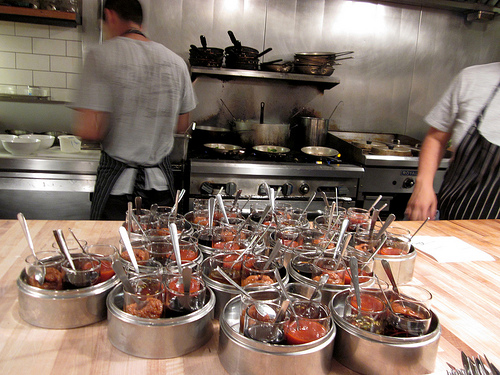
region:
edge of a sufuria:
[238, 336, 275, 366]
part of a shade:
[68, 338, 82, 352]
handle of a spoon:
[263, 272, 290, 296]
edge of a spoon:
[322, 220, 362, 282]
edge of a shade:
[102, 355, 124, 365]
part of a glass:
[299, 292, 322, 329]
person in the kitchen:
[66, 13, 201, 161]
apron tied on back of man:
[101, 150, 181, 195]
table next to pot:
[455, 276, 482, 299]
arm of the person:
[383, 119, 460, 230]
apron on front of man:
[446, 118, 496, 176]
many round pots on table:
[96, 186, 403, 354]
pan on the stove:
[311, 136, 339, 163]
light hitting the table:
[451, 286, 481, 338]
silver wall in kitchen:
[368, 36, 424, 73]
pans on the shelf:
[206, 38, 348, 88]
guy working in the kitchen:
[66, 19, 196, 171]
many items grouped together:
[113, 185, 387, 347]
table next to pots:
[435, 258, 480, 308]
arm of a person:
[365, 131, 465, 238]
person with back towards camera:
[82, 8, 179, 152]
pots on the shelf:
[203, 33, 346, 96]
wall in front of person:
[7, 42, 54, 82]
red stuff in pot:
[293, 314, 324, 349]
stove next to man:
[224, 114, 321, 163]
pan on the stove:
[288, 126, 344, 183]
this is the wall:
[9, 30, 58, 65]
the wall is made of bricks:
[6, 30, 62, 82]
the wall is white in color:
[8, 25, 51, 68]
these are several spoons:
[76, 207, 368, 294]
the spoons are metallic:
[91, 213, 313, 267]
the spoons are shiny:
[110, 222, 190, 263]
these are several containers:
[46, 300, 453, 374]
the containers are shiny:
[145, 327, 188, 350]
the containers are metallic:
[41, 299, 128, 336]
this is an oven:
[200, 161, 359, 182]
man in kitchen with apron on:
[57, 0, 219, 230]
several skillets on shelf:
[180, 22, 362, 102]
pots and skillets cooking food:
[186, 89, 351, 187]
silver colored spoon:
[6, 209, 55, 285]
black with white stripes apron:
[422, 64, 497, 219]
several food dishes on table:
[9, 162, 443, 373]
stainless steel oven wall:
[145, 5, 451, 147]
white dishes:
[0, 124, 64, 168]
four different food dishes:
[102, 223, 216, 362]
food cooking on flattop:
[332, 114, 465, 236]